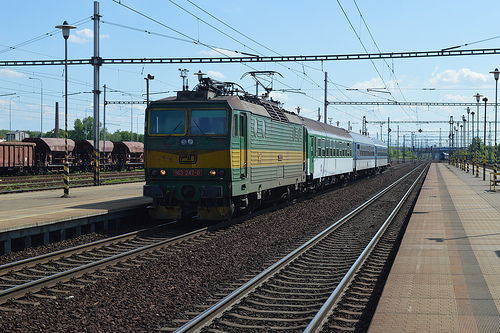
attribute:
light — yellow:
[209, 169, 219, 176]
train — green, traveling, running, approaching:
[143, 80, 392, 223]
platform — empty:
[366, 162, 499, 332]